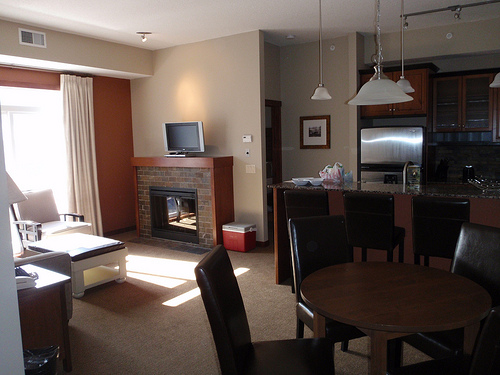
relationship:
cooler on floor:
[222, 222, 258, 252] [55, 214, 499, 372]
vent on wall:
[16, 25, 49, 48] [0, 20, 152, 79]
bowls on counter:
[289, 173, 326, 187] [265, 177, 498, 287]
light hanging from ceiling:
[304, 0, 335, 102] [1, 2, 497, 51]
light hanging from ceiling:
[343, 0, 414, 107] [1, 2, 497, 51]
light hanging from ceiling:
[395, 1, 415, 93] [1, 2, 497, 51]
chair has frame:
[5, 189, 90, 246] [12, 191, 132, 291]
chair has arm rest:
[5, 189, 94, 248] [54, 207, 86, 225]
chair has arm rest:
[5, 189, 94, 248] [11, 215, 43, 239]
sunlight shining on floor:
[116, 232, 236, 313] [54, 231, 425, 373]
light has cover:
[343, 0, 414, 107] [350, 75, 410, 110]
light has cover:
[304, 0, 335, 102] [307, 85, 336, 104]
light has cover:
[395, 1, 415, 93] [386, 69, 422, 96]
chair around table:
[192, 243, 334, 375] [294, 255, 496, 374]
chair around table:
[286, 214, 368, 361] [294, 255, 496, 374]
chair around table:
[401, 223, 497, 373] [294, 255, 496, 374]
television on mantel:
[163, 117, 209, 159] [129, 150, 234, 247]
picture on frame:
[297, 113, 331, 150] [292, 110, 333, 157]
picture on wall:
[303, 119, 327, 145] [280, 32, 349, 184]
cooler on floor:
[218, 215, 257, 250] [147, 240, 190, 308]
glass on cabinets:
[431, 75, 468, 140] [427, 69, 484, 138]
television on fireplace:
[161, 121, 205, 156] [132, 159, 217, 241]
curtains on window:
[60, 67, 102, 215] [2, 102, 60, 172]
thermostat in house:
[239, 133, 255, 146] [9, 10, 484, 364]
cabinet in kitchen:
[437, 77, 499, 133] [0, 2, 498, 369]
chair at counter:
[341, 189, 406, 268] [267, 175, 499, 200]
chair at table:
[201, 275, 270, 370] [308, 262, 410, 344]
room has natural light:
[2, 8, 492, 369] [8, 86, 160, 291]